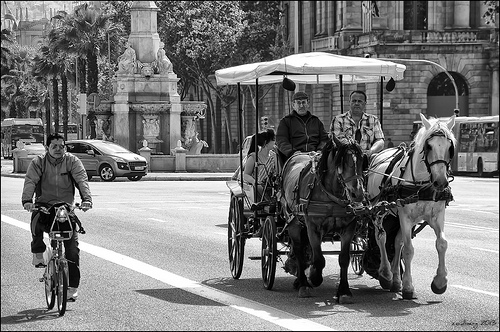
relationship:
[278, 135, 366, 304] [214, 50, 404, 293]
horse pulling carriage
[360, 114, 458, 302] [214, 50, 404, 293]
horse pulling carriage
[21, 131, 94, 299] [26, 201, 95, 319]
person on bike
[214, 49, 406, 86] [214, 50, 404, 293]
canopy on carriage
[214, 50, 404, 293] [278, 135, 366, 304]
carriage with horse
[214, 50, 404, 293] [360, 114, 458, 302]
carriage with horse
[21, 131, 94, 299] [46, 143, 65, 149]
person has glasses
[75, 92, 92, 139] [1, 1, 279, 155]
light under trees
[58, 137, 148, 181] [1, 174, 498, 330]
car in road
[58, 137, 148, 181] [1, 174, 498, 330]
car on road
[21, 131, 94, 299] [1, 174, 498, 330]
person on road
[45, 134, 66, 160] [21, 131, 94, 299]
head on person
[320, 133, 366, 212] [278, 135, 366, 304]
head on horse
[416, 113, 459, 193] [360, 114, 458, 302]
head on horse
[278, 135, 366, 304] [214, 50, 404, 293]
horse on carriage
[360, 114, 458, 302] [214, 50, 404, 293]
horse on carriage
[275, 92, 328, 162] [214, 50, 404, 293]
person on carriage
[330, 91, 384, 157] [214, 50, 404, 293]
person on carriage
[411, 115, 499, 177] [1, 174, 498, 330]
bus on road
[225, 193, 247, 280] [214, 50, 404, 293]
wheel on carriage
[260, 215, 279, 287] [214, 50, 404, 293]
wheel on carriage